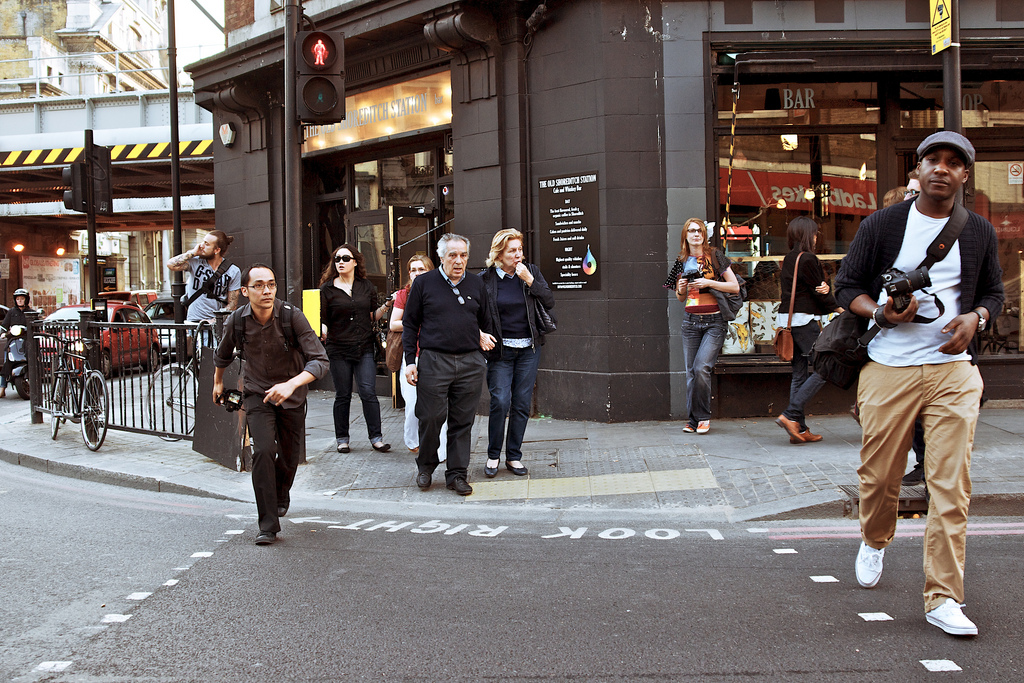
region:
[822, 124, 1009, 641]
man is crossing the road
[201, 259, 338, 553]
man is rushing across the road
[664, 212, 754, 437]
woman is standing outside a store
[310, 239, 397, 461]
woman in a black shirt wears sunglasses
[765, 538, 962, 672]
small white squares on the road mark a crossing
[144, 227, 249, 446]
a man holding a bicycle is holding a phone to his ear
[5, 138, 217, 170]
black and yellow hazard markings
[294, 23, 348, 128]
pedestrian light is red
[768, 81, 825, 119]
the word bar on a window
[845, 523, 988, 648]
Man wearing shoes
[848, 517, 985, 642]
Man is wearing shoes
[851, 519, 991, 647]
Man wearing white shoes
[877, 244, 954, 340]
Man holding a camera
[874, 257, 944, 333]
Man is holding a camera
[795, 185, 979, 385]
Man carrying a bag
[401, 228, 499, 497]
elderly man wearing dark sweater and black pants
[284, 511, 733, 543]
white lettering on the street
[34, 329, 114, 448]
bicycle leaning against black railing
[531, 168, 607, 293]
black sign with white writing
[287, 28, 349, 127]
lit pedestrian crossing sign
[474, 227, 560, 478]
woman wearing a dark sweater and dark pants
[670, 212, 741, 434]
woman with red hair wearing dark jeans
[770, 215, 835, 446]
dark haired woman with brown purse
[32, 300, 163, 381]
red car behind the railing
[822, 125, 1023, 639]
Man is facing the camera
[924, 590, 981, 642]
Right white shoe on a man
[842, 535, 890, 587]
Left shoe on a man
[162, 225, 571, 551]
Several people are walking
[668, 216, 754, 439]
Woman is visible and standing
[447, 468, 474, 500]
Right shoe of a man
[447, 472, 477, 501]
Right black shoe of a man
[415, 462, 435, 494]
Left shoe of a man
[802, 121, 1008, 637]
man wearing tan pants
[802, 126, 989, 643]
man carrying a camera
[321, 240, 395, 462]
woman wearing sunglasses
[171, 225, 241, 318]
man wearing gray tshirt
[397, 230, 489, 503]
man with sunglasses on his sweater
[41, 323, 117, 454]
bicycle parked on sidewalk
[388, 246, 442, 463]
woman wearing red shirt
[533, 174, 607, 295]
sign on building front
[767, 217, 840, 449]
woman with brown purse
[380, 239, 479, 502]
a perosn on the sidewalk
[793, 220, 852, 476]
a perosn on the sidewalk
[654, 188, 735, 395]
a perosn on the sidewalk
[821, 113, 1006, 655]
man holding a camera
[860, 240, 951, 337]
the camera is black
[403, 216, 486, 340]
man is old and has gray hair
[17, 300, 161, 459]
bike leans on a rail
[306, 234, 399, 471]
woman has long hair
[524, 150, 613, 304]
a sign on a wall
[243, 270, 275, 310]
person has a head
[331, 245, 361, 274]
person has a head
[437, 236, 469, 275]
person has a head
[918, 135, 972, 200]
person has a head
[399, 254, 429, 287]
person has a head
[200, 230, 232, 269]
person has a head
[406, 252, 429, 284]
person has a head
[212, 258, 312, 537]
person on the street corner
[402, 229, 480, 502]
person on the street corner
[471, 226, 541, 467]
person on the street corner